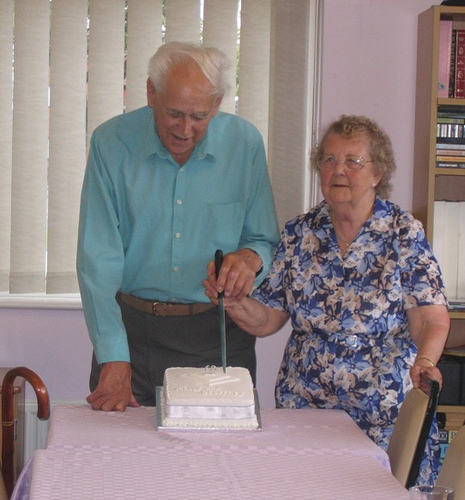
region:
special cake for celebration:
[152, 362, 265, 437]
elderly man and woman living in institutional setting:
[67, 36, 456, 447]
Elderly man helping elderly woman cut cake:
[50, 39, 462, 440]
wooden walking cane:
[1, 361, 52, 499]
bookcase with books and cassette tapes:
[408, 17, 464, 265]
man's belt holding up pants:
[114, 287, 220, 321]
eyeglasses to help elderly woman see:
[306, 150, 383, 177]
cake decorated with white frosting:
[152, 359, 264, 433]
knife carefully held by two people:
[203, 243, 264, 376]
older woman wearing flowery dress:
[225, 111, 456, 490]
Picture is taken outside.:
[31, 19, 457, 456]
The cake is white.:
[140, 364, 288, 454]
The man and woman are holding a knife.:
[201, 246, 266, 368]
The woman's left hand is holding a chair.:
[388, 245, 449, 427]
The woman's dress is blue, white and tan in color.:
[283, 227, 405, 428]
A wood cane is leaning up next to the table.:
[10, 345, 71, 497]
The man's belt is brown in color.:
[109, 272, 238, 343]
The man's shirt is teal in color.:
[116, 183, 268, 226]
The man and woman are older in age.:
[101, 3, 425, 230]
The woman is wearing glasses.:
[303, 134, 414, 197]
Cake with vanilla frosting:
[154, 361, 262, 436]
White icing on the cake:
[152, 364, 262, 435]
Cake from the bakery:
[154, 362, 262, 433]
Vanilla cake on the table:
[154, 362, 262, 434]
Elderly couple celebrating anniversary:
[74, 41, 451, 435]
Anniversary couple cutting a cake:
[74, 39, 449, 498]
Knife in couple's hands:
[151, 248, 261, 371]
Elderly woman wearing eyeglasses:
[306, 114, 395, 206]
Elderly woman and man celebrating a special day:
[76, 38, 451, 436]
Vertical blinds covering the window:
[0, 2, 308, 293]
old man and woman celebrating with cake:
[94, 40, 388, 408]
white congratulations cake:
[136, 349, 273, 436]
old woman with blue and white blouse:
[267, 104, 434, 327]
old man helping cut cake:
[59, 73, 294, 335]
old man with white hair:
[97, 37, 257, 270]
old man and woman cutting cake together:
[83, 29, 413, 418]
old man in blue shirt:
[62, 42, 271, 324]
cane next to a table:
[0, 342, 69, 484]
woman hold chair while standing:
[268, 98, 443, 489]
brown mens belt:
[106, 268, 246, 341]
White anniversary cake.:
[155, 366, 257, 429]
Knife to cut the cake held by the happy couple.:
[212, 249, 233, 377]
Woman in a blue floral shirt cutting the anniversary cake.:
[223, 116, 452, 486]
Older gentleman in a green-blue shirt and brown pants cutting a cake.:
[83, 41, 283, 411]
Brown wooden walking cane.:
[1, 369, 51, 494]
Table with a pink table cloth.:
[40, 401, 413, 497]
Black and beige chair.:
[389, 374, 439, 487]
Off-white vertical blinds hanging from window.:
[3, 2, 316, 309]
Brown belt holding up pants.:
[118, 293, 248, 317]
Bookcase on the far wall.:
[417, 9, 462, 378]